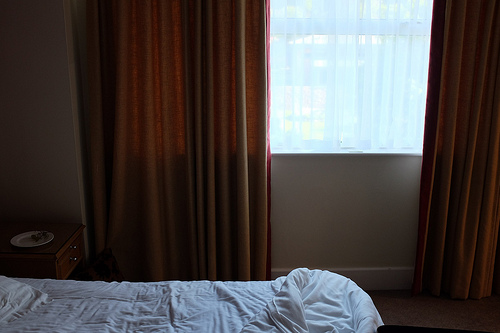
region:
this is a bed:
[0, 265, 377, 331]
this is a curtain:
[74, 0, 291, 287]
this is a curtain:
[422, 2, 499, 314]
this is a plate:
[12, 215, 61, 255]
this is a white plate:
[10, 214, 52, 254]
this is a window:
[119, 2, 441, 157]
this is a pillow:
[2, 278, 52, 320]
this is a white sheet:
[235, 258, 387, 331]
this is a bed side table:
[4, 210, 90, 284]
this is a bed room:
[0, 0, 499, 330]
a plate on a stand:
[12, 226, 54, 255]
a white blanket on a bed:
[57, 273, 366, 325]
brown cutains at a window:
[99, 2, 272, 269]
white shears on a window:
[265, 4, 425, 158]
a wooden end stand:
[16, 227, 85, 276]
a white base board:
[357, 263, 419, 297]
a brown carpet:
[387, 300, 492, 325]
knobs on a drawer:
[67, 244, 81, 268]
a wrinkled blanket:
[251, 277, 361, 324]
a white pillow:
[4, 273, 37, 330]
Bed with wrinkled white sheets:
[6, 265, 386, 332]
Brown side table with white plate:
[6, 210, 95, 285]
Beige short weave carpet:
[376, 288, 496, 330]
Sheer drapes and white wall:
[275, 8, 429, 295]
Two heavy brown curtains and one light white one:
[64, 8, 494, 298]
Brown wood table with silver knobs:
[6, 217, 96, 279]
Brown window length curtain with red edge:
[66, 4, 284, 286]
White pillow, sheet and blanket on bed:
[4, 271, 389, 332]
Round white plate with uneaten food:
[12, 221, 60, 253]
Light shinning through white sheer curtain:
[271, 8, 423, 292]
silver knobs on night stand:
[72, 242, 79, 265]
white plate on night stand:
[6, 227, 56, 249]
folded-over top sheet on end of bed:
[229, 263, 382, 331]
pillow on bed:
[1, 267, 52, 332]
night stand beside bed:
[3, 222, 96, 281]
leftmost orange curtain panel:
[72, 2, 274, 281]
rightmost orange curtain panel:
[410, 2, 498, 302]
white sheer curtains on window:
[267, 1, 434, 156]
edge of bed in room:
[1, 272, 386, 330]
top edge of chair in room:
[373, 322, 498, 331]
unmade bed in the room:
[19, 277, 379, 329]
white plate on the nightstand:
[6, 223, 58, 253]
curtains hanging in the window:
[73, 0, 281, 220]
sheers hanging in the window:
[279, 16, 408, 160]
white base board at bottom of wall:
[341, 260, 418, 296]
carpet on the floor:
[397, 299, 482, 326]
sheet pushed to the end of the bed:
[237, 283, 301, 331]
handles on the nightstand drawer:
[67, 240, 82, 264]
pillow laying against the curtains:
[76, 243, 128, 279]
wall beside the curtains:
[19, 22, 65, 153]